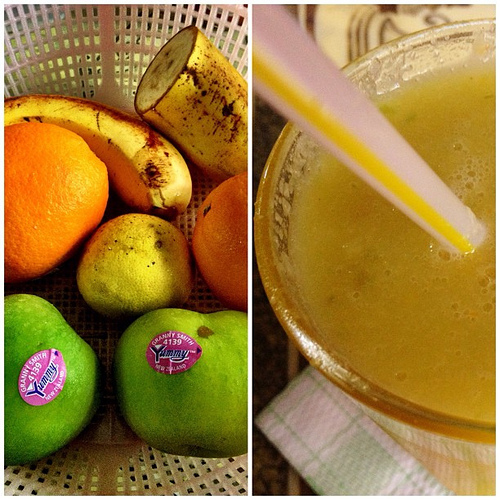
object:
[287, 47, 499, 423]
bubble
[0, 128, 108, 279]
orange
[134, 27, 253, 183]
banana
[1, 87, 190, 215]
banana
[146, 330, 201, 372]
label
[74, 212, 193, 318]
lemon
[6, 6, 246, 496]
basket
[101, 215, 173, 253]
bruises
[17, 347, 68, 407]
label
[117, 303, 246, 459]
apple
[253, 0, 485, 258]
straw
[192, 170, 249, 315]
orange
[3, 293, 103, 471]
apple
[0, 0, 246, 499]
basket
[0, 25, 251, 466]
fruit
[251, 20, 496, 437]
glass